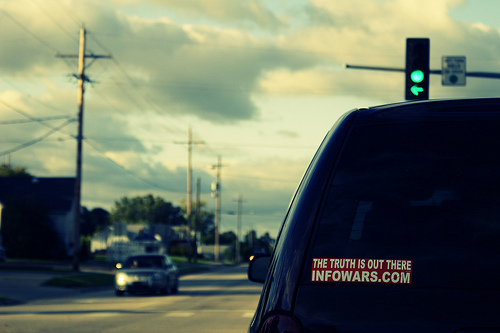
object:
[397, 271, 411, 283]
letters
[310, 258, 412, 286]
bumper sticker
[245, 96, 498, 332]
car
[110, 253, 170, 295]
car front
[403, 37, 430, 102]
trafficlight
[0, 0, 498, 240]
clouds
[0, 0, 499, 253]
sky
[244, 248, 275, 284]
side mirror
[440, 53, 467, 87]
sign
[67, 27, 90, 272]
utility pole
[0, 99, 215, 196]
powerlines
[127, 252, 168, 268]
windshield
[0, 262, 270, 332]
street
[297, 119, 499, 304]
window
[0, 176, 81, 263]
houses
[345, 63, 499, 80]
pole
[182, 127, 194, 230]
utility poles